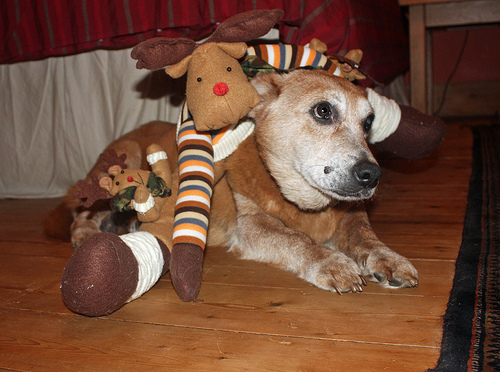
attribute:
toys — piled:
[61, 24, 402, 283]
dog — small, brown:
[199, 60, 387, 280]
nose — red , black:
[355, 148, 389, 179]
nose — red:
[193, 75, 243, 121]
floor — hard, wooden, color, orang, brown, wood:
[394, 166, 452, 236]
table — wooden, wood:
[392, 8, 456, 54]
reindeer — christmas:
[117, 17, 282, 169]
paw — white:
[333, 253, 427, 278]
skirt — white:
[219, 117, 259, 145]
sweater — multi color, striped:
[162, 117, 229, 247]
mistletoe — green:
[133, 157, 189, 213]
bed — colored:
[8, 18, 128, 135]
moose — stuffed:
[97, 141, 182, 242]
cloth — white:
[3, 66, 151, 171]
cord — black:
[426, 30, 479, 91]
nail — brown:
[339, 262, 445, 328]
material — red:
[308, 7, 378, 40]